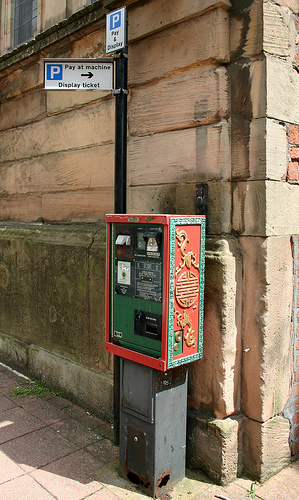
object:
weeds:
[6, 378, 63, 397]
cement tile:
[0, 423, 82, 474]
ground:
[0, 360, 298, 498]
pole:
[114, 7, 127, 446]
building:
[0, 0, 297, 486]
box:
[105, 212, 205, 370]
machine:
[103, 211, 204, 371]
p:
[109, 11, 122, 28]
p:
[49, 64, 61, 80]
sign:
[43, 56, 115, 91]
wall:
[263, 0, 297, 478]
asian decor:
[175, 270, 199, 308]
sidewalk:
[0, 361, 296, 497]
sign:
[106, 5, 126, 54]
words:
[110, 28, 115, 36]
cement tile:
[254, 465, 298, 498]